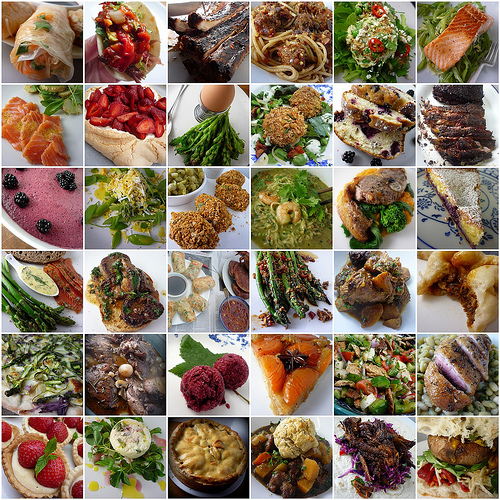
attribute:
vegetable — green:
[174, 116, 244, 164]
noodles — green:
[418, 1, 491, 83]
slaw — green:
[345, 5, 412, 71]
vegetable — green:
[183, 122, 238, 169]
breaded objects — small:
[172, 169, 252, 249]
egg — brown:
[200, 87, 229, 109]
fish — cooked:
[417, 7, 499, 90]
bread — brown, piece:
[15, 250, 63, 262]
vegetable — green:
[335, 16, 417, 88]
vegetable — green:
[94, 174, 165, 241]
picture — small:
[6, 2, 498, 498]